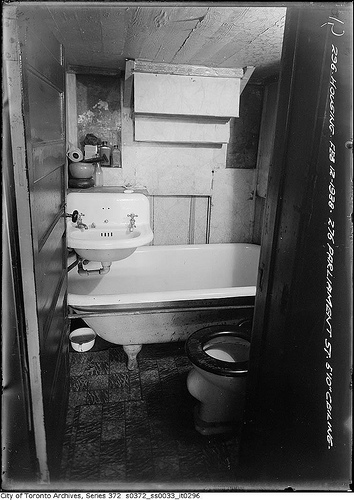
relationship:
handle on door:
[67, 208, 81, 224] [10, 16, 81, 485]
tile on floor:
[87, 363, 107, 374] [70, 367, 167, 471]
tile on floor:
[76, 359, 88, 375] [76, 373, 184, 472]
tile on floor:
[88, 373, 106, 391] [78, 370, 177, 462]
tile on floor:
[90, 375, 109, 387] [79, 368, 169, 468]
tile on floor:
[107, 375, 126, 386] [66, 382, 154, 462]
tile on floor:
[98, 377, 116, 396] [82, 381, 150, 459]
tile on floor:
[88, 376, 107, 386] [78, 377, 157, 458]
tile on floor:
[83, 390, 109, 406] [80, 388, 164, 469]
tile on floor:
[107, 388, 124, 401] [93, 374, 174, 459]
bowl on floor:
[69, 327, 102, 355] [58, 368, 187, 484]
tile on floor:
[91, 423, 126, 447] [76, 411, 92, 424]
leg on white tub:
[113, 342, 153, 370] [64, 243, 268, 370]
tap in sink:
[69, 210, 88, 222] [76, 218, 143, 241]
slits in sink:
[97, 225, 116, 237] [69, 220, 142, 244]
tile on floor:
[89, 381, 111, 391] [60, 385, 181, 473]